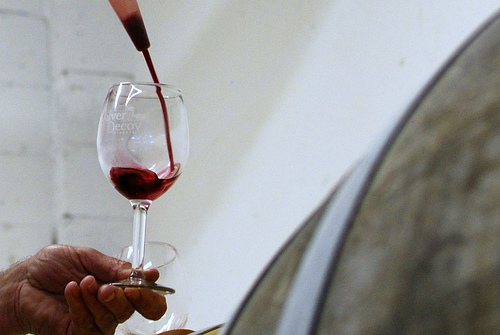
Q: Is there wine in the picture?
A: Yes, there is wine.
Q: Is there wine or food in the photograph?
A: Yes, there is wine.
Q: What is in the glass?
A: The wine is in the glass.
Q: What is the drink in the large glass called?
A: The drink is wine.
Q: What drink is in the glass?
A: The drink is wine.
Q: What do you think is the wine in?
A: The wine is in the glass.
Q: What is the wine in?
A: The wine is in the glass.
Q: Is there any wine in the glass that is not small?
A: Yes, there is wine in the glass.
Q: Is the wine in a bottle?
A: No, the wine is in a glass.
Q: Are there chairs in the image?
A: No, there are no chairs.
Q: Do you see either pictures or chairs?
A: No, there are no chairs or pictures.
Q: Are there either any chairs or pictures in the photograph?
A: No, there are no chairs or pictures.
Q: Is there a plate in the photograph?
A: No, there are no plates.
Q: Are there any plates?
A: No, there are no plates.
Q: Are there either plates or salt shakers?
A: No, there are no plates or salt shakers.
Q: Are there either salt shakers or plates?
A: No, there are no plates or salt shakers.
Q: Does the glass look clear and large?
A: Yes, the glass is clear and large.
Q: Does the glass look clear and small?
A: No, the glass is clear but large.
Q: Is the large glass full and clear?
A: No, the glass is clear but empty.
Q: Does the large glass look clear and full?
A: No, the glass is clear but empty.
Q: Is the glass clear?
A: Yes, the glass is clear.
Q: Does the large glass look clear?
A: Yes, the glass is clear.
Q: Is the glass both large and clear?
A: Yes, the glass is large and clear.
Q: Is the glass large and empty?
A: Yes, the glass is large and empty.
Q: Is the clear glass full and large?
A: No, the glass is large but empty.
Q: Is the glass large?
A: Yes, the glass is large.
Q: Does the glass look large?
A: Yes, the glass is large.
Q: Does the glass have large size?
A: Yes, the glass is large.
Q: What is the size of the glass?
A: The glass is large.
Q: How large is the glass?
A: The glass is large.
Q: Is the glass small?
A: No, the glass is large.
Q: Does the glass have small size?
A: No, the glass is large.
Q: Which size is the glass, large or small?
A: The glass is large.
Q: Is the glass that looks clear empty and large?
A: Yes, the glass is empty and large.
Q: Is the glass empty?
A: Yes, the glass is empty.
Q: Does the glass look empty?
A: Yes, the glass is empty.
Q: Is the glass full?
A: No, the glass is empty.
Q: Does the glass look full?
A: No, the glass is empty.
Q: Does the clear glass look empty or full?
A: The glass is empty.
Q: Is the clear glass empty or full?
A: The glass is empty.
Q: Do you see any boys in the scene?
A: No, there are no boys.